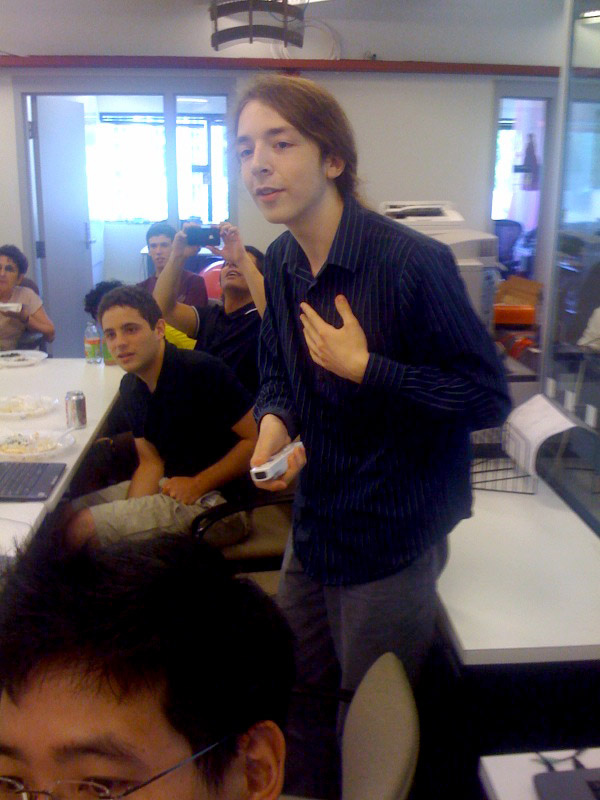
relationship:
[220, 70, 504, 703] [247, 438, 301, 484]
man holding controller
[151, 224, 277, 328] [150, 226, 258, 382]
man holding up phone